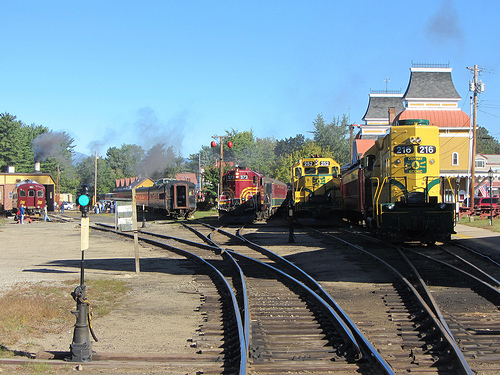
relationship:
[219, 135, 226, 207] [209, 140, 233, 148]
light on pole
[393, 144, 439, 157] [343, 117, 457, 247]
number on train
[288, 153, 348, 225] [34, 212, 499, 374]
train on tracks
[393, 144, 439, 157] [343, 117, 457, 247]
number at train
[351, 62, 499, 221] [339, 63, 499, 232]
buildig at back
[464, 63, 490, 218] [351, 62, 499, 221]
pole at buildig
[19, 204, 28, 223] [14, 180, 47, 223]
people at train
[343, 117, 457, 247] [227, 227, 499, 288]
train has shadow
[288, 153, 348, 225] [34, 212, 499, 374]
train at tracks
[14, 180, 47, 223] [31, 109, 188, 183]
train has smoke